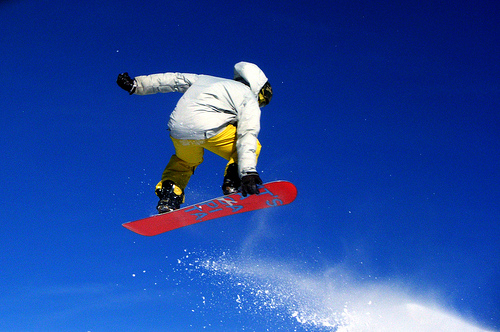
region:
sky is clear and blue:
[60, 82, 465, 292]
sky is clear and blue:
[88, 177, 474, 274]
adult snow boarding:
[93, 46, 340, 306]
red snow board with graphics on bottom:
[115, 172, 336, 247]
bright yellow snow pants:
[160, 111, 260, 221]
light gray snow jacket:
[130, 21, 265, 178]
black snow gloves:
[235, 167, 275, 203]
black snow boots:
[150, 165, 191, 230]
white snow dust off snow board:
[162, 235, 402, 325]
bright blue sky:
[320, 45, 460, 145]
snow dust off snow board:
[350, 276, 412, 323]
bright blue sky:
[27, 20, 114, 122]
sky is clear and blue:
[370, 118, 472, 233]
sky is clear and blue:
[306, 106, 442, 267]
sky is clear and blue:
[230, 265, 445, 328]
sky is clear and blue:
[197, 212, 490, 293]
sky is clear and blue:
[322, 141, 478, 312]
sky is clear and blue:
[10, 108, 106, 324]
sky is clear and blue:
[351, 90, 499, 287]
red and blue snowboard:
[114, 179, 301, 236]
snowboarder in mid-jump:
[102, 48, 300, 239]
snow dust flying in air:
[180, 232, 495, 328]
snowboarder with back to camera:
[100, 43, 335, 270]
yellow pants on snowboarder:
[145, 120, 275, 211]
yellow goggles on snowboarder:
[255, 80, 271, 105]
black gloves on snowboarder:
[113, 68, 138, 93]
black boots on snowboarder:
[150, 177, 185, 215]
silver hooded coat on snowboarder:
[135, 32, 273, 167]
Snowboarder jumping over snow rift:
[57, 8, 497, 329]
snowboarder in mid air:
[94, 57, 331, 244]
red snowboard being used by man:
[119, 181, 308, 243]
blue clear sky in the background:
[320, 9, 485, 239]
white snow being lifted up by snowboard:
[205, 259, 482, 329]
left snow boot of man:
[143, 183, 188, 217]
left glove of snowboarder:
[109, 62, 139, 97]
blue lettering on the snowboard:
[179, 194, 256, 220]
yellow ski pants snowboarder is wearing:
[154, 132, 250, 186]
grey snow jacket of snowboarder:
[149, 59, 279, 134]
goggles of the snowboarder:
[259, 94, 272, 109]